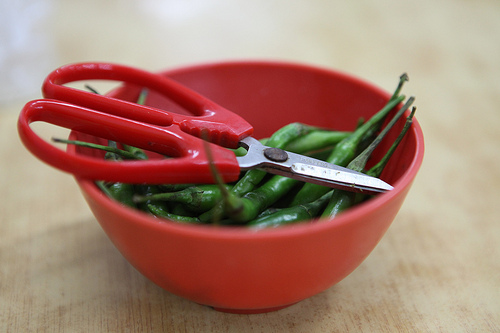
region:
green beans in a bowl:
[161, 77, 346, 250]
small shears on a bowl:
[53, 62, 362, 211]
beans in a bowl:
[203, 147, 285, 210]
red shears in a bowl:
[51, 55, 251, 217]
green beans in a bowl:
[246, 98, 353, 173]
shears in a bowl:
[22, 38, 260, 203]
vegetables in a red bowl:
[237, 167, 298, 215]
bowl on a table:
[56, 56, 417, 319]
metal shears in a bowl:
[222, 112, 400, 232]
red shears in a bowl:
[37, 62, 177, 150]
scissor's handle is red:
[43, 78, 348, 230]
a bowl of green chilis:
[116, 56, 391, 310]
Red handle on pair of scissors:
[17, 60, 252, 180]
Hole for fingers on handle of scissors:
[26, 120, 186, 160]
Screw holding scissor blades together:
[260, 145, 285, 160]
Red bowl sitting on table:
[66, 55, 421, 310]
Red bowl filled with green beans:
[65, 55, 421, 310]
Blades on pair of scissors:
[236, 145, 387, 190]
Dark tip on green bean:
[395, 70, 410, 89]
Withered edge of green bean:
[345, 91, 415, 171]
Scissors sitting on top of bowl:
[15, 57, 421, 312]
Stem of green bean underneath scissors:
[47, 132, 137, 148]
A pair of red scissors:
[18, 59, 368, 185]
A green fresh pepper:
[197, 134, 274, 209]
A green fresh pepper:
[136, 189, 221, 204]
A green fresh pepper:
[147, 201, 193, 223]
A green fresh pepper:
[257, 196, 315, 233]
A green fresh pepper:
[265, 100, 309, 147]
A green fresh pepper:
[327, 106, 381, 161]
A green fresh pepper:
[56, 139, 143, 159]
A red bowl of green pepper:
[40, 64, 389, 308]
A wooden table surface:
[395, 246, 490, 331]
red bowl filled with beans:
[13, 45, 434, 303]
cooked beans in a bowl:
[14, 50, 455, 319]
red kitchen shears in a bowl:
[15, 38, 437, 313]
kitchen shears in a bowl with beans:
[15, 39, 442, 310]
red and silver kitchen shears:
[12, 48, 410, 206]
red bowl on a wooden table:
[12, 37, 461, 318]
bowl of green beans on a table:
[13, 43, 461, 320]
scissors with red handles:
[10, 47, 409, 207]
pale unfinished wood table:
[5, 310, 494, 330]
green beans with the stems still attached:
[317, 67, 427, 157]